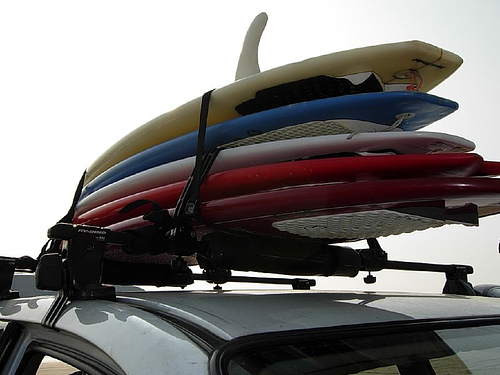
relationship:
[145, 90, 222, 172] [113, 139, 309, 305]
strap for luggage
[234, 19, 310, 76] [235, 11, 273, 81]
fin on fin